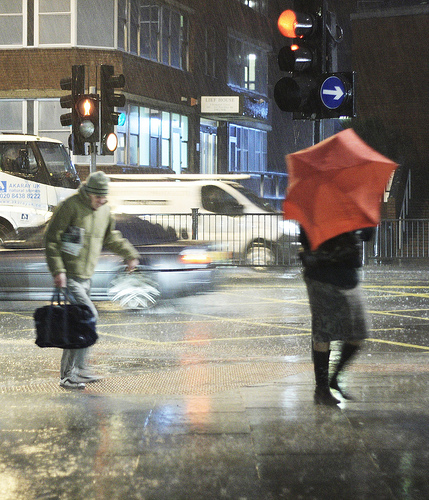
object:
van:
[93, 174, 300, 274]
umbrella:
[278, 124, 398, 248]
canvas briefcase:
[30, 296, 100, 350]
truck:
[0, 136, 86, 231]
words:
[26, 192, 41, 199]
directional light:
[321, 73, 343, 108]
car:
[0, 214, 218, 308]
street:
[0, 219, 425, 388]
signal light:
[78, 99, 95, 120]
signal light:
[117, 112, 127, 127]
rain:
[112, 346, 145, 354]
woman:
[299, 134, 382, 413]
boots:
[310, 387, 344, 410]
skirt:
[307, 291, 369, 341]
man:
[37, 170, 141, 395]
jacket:
[47, 195, 137, 277]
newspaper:
[59, 227, 86, 258]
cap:
[79, 171, 109, 194]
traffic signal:
[275, 8, 300, 41]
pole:
[330, 12, 342, 74]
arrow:
[323, 87, 341, 99]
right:
[332, 86, 344, 100]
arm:
[43, 208, 64, 273]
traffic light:
[104, 132, 118, 154]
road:
[124, 423, 429, 500]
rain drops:
[401, 263, 417, 315]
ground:
[240, 402, 254, 417]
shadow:
[159, 279, 211, 300]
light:
[229, 295, 244, 304]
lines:
[385, 340, 427, 350]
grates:
[121, 385, 124, 389]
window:
[36, 143, 75, 188]